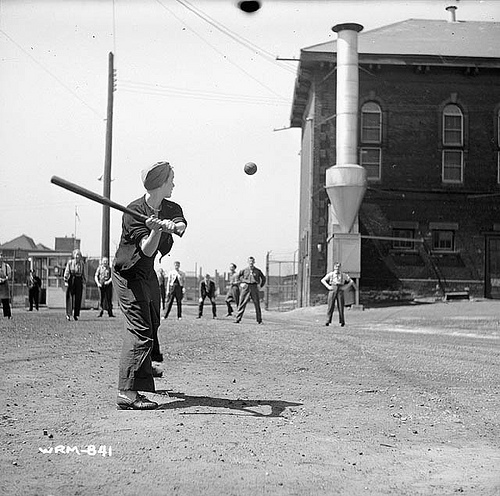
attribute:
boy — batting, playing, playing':
[105, 152, 186, 418]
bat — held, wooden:
[43, 174, 182, 236]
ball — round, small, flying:
[241, 161, 257, 177]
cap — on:
[136, 159, 175, 192]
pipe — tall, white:
[323, 18, 373, 291]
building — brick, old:
[270, 4, 499, 310]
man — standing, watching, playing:
[317, 260, 356, 331]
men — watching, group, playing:
[5, 252, 272, 318]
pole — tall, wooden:
[100, 47, 116, 300]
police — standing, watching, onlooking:
[23, 267, 48, 310]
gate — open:
[266, 249, 305, 313]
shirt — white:
[321, 271, 353, 289]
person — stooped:
[197, 270, 221, 323]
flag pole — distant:
[72, 205, 80, 252]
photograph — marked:
[3, 3, 500, 495]